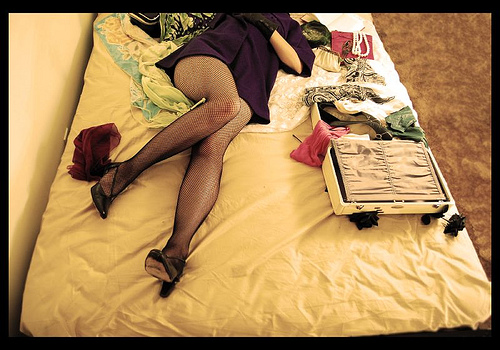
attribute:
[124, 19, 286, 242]
woman — lying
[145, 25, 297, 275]
woman — lying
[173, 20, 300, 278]
woman — lying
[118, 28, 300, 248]
woman — lying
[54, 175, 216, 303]
shoes — black, high heeled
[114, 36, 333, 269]
person — laying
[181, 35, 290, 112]
coat — purple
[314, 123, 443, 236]
valise — white, opened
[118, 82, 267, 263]
fishnets — worn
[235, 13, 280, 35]
glove — black, leather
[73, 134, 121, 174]
scarf — purple, translucent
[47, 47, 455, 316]
bed — covered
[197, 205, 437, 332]
sheets — white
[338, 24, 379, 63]
necklaces — white, pearls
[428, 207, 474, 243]
rose — black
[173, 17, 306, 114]
dress — purple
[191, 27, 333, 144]
dress — purple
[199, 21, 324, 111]
dress — purple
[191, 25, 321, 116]
dress — purple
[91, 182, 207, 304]
shoes — black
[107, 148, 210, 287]
shoes — black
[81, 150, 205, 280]
shoes — black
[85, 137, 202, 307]
shoes — black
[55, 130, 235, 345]
shoes — black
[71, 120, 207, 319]
heels — black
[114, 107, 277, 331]
pantyhose — black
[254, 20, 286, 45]
gloves — black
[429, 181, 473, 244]
flower — black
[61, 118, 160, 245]
object — red 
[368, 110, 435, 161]
item — green 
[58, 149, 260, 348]
shoes — black 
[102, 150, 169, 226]
socks — black 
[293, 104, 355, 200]
skirt — purple , short 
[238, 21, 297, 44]
gloves — black 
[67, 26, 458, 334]
bed sheet — white 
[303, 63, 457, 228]
suitcase — white 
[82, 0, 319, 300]
woman — white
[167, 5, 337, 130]
outfit — purple 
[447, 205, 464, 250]
rose — black, silk 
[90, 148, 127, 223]
shoe — black , leather, high heeled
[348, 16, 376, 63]
pearls — strand , white  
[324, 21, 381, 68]
pouch — red, Leather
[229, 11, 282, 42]
gloves — Leather, black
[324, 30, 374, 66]
scarf — wine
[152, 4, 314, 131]
dress — short, plum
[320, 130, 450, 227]
suitcase — small, white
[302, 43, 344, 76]
makeup bag — creamy, leather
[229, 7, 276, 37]
glove — black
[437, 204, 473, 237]
flower — black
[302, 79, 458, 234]
luggage — white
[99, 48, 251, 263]
hills — black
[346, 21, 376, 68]
necklace — white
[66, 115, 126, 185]
scarf — red